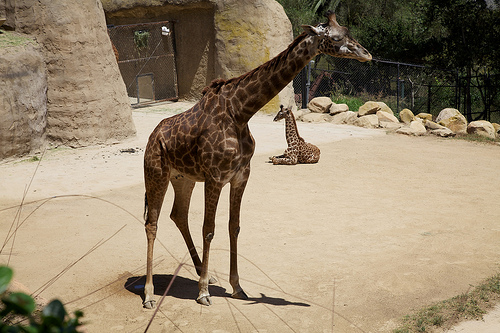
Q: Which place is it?
A: It is a zoo.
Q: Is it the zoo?
A: Yes, it is the zoo.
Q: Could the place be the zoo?
A: Yes, it is the zoo.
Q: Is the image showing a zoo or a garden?
A: It is showing a zoo.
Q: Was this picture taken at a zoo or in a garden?
A: It was taken at a zoo.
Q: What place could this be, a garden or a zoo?
A: It is a zoo.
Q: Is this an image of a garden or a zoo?
A: It is showing a zoo.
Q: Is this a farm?
A: No, it is a zoo.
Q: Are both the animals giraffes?
A: Yes, all the animals are giraffes.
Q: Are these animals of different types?
A: No, all the animals are giraffes.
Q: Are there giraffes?
A: Yes, there is a giraffe.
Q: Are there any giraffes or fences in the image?
A: Yes, there is a giraffe.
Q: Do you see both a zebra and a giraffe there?
A: No, there is a giraffe but no zebras.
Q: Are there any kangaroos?
A: No, there are no kangaroos.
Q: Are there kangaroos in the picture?
A: No, there are no kangaroos.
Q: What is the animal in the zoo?
A: The animal is a giraffe.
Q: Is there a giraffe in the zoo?
A: Yes, there is a giraffe in the zoo.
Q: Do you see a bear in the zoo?
A: No, there is a giraffe in the zoo.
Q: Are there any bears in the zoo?
A: No, there is a giraffe in the zoo.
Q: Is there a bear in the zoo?
A: No, there is a giraffe in the zoo.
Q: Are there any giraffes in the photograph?
A: Yes, there is a giraffe.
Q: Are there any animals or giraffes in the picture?
A: Yes, there is a giraffe.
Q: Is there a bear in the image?
A: No, there are no bears.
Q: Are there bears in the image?
A: No, there are no bears.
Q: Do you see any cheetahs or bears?
A: No, there are no bears or cheetahs.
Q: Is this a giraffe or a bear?
A: This is a giraffe.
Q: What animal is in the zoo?
A: The giraffe is in the zoo.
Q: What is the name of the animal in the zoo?
A: The animal is a giraffe.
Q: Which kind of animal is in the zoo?
A: The animal is a giraffe.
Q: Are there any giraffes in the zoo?
A: Yes, there is a giraffe in the zoo.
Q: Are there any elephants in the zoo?
A: No, there is a giraffe in the zoo.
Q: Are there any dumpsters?
A: No, there are no dumpsters.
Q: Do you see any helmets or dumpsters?
A: No, there are no dumpsters or helmets.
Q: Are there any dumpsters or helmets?
A: No, there are no dumpsters or helmets.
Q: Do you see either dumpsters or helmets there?
A: No, there are no dumpsters or helmets.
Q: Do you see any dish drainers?
A: No, there are no dish drainers.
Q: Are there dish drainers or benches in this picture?
A: No, there are no dish drainers or benches.